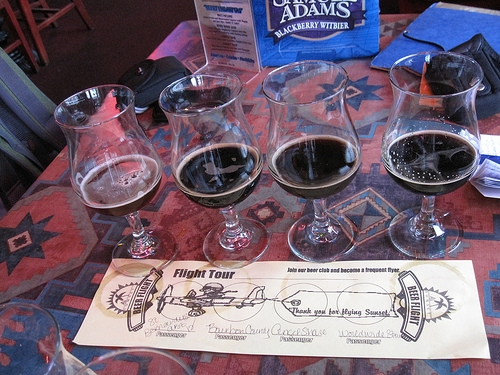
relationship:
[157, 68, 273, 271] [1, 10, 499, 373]
glass on table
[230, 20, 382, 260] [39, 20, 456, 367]
glass on table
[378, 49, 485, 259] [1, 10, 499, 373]
glass on table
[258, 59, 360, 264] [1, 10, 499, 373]
glass on table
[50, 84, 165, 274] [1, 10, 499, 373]
glass on table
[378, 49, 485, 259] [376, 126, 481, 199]
glass has brown liquid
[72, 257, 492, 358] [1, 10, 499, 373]
menu on table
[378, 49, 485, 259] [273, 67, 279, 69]
glass has rim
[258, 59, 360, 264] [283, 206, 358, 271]
glass has base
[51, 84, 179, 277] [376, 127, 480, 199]
glass with brown liquid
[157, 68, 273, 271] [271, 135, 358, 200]
glass with liquid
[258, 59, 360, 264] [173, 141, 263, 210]
glass with liquid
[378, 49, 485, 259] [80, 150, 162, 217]
glass with liquid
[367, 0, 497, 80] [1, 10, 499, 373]
blue folder on table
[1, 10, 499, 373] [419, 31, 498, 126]
table under black case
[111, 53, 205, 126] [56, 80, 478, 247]
black case behind glasses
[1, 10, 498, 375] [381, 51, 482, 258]
table in front of glasses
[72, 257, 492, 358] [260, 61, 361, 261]
menu in front of glasses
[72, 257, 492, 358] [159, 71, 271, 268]
menu in front of glasses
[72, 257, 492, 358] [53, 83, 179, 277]
menu in front of glasses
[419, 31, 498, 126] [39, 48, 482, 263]
black case behind glasses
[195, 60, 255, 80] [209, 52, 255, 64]
clear stand with blue lettering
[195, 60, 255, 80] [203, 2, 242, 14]
clear stand with blue lettering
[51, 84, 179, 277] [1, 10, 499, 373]
glass on table